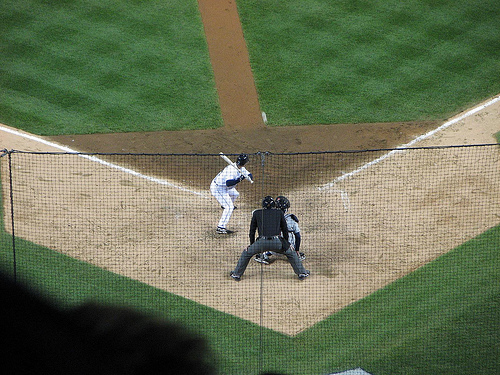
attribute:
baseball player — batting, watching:
[205, 149, 256, 235]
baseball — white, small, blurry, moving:
[262, 111, 269, 123]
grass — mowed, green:
[2, 1, 497, 375]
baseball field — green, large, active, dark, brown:
[3, 2, 500, 372]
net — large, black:
[2, 147, 499, 372]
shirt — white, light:
[215, 160, 250, 184]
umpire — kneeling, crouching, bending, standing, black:
[231, 194, 311, 282]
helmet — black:
[236, 152, 251, 164]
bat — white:
[216, 152, 255, 185]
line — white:
[2, 124, 204, 203]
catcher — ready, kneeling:
[256, 195, 307, 262]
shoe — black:
[216, 225, 228, 236]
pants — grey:
[237, 239, 307, 275]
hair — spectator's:
[3, 271, 216, 373]